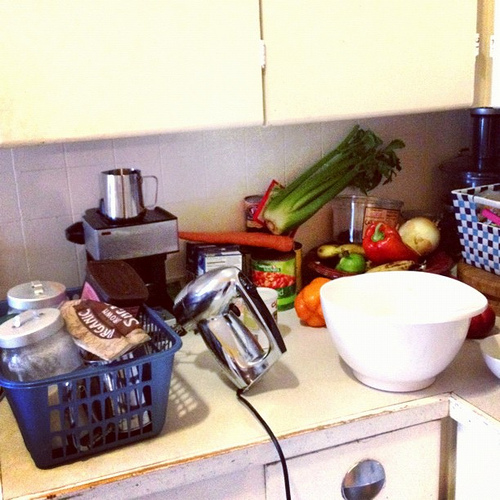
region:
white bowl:
[310, 261, 488, 366]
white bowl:
[354, 277, 465, 418]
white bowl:
[305, 302, 496, 447]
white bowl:
[272, 277, 440, 412]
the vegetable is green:
[256, 120, 418, 233]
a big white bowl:
[313, 267, 491, 394]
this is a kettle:
[171, 260, 288, 402]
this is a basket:
[3, 295, 186, 462]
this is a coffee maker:
[68, 163, 187, 335]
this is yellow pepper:
[295, 275, 345, 333]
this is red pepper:
[357, 195, 422, 268]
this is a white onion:
[401, 218, 451, 252]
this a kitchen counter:
[11, 95, 499, 493]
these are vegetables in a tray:
[311, 215, 456, 277]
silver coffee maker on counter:
[44, 135, 166, 355]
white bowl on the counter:
[336, 239, 476, 382]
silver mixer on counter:
[191, 226, 321, 421]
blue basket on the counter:
[54, 304, 206, 491]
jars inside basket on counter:
[6, 267, 98, 447]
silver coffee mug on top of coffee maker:
[46, 145, 205, 230]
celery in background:
[123, 117, 438, 272]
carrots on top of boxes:
[121, 205, 333, 312]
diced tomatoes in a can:
[218, 229, 315, 324]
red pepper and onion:
[371, 176, 458, 279]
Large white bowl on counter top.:
[348, 265, 439, 373]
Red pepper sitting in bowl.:
[363, 220, 410, 277]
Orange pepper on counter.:
[291, 292, 316, 317]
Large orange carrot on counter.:
[190, 210, 283, 262]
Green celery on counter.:
[272, 152, 334, 219]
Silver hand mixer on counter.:
[182, 273, 304, 408]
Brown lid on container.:
[89, 261, 142, 317]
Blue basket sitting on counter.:
[19, 369, 170, 423]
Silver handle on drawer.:
[341, 458, 406, 495]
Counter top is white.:
[183, 392, 269, 414]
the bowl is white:
[249, 214, 456, 420]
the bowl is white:
[302, 177, 497, 462]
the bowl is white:
[328, 218, 481, 379]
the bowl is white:
[276, 268, 419, 498]